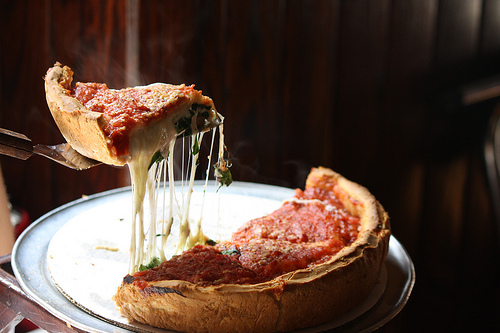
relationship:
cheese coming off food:
[127, 125, 217, 222] [46, 51, 262, 206]